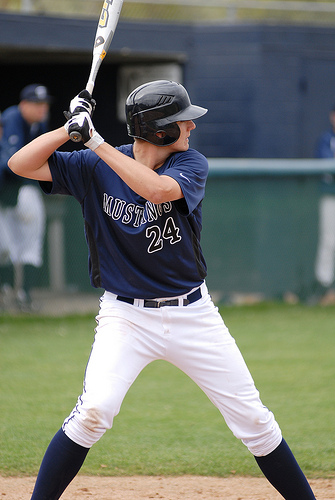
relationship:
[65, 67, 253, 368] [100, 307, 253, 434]
boy wearing pants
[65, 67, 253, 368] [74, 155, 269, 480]
boy wearing uniform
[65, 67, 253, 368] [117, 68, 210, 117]
boy wearing helmet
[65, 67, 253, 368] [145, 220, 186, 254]
boy number 24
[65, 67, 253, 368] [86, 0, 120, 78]
boy holding bat